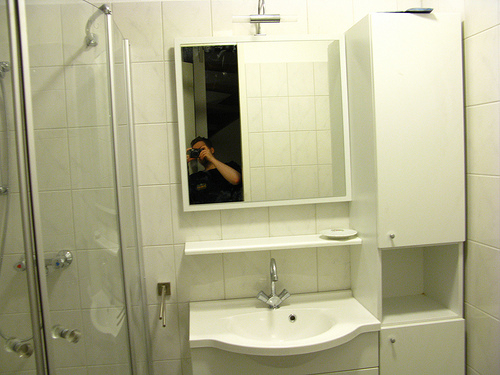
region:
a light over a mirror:
[234, 8, 284, 28]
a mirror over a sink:
[164, 29, 354, 212]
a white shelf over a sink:
[180, 225, 358, 260]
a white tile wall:
[165, 256, 266, 296]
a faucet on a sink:
[261, 254, 294, 310]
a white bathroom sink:
[181, 280, 381, 360]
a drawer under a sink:
[189, 328, 387, 374]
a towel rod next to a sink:
[153, 272, 176, 334]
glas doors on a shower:
[1, 3, 158, 373]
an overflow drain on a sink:
[284, 310, 299, 321]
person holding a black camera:
[185, 133, 240, 203]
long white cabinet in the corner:
[344, 18, 475, 255]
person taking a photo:
[183, 131, 242, 201]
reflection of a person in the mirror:
[183, 135, 242, 202]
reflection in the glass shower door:
[74, 188, 127, 356]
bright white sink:
[186, 288, 374, 357]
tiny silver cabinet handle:
[383, 230, 403, 244]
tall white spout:
[251, 259, 296, 311]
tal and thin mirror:
[179, 46, 256, 208]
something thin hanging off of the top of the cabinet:
[382, 5, 432, 17]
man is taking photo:
[173, 123, 298, 210]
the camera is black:
[182, 136, 207, 165]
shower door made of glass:
[1, 1, 175, 373]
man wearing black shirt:
[184, 160, 249, 218]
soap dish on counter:
[299, 211, 391, 256]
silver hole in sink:
[279, 309, 304, 326]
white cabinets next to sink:
[343, 8, 498, 373]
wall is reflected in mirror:
[240, 59, 340, 194]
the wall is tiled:
[130, 4, 492, 365]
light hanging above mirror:
[230, 2, 301, 41]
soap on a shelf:
[313, 225, 361, 242]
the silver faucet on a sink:
[256, 254, 293, 307]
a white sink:
[183, 284, 383, 356]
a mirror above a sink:
[170, 33, 357, 207]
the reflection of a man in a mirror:
[180, 119, 244, 201]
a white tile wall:
[149, 212, 225, 293]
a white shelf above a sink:
[178, 219, 366, 267]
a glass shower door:
[2, 2, 157, 373]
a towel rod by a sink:
[156, 275, 177, 333]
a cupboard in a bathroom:
[342, 9, 475, 251]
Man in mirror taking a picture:
[158, 58, 245, 206]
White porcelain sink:
[167, 270, 344, 372]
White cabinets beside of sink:
[363, 57, 488, 372]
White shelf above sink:
[175, 227, 378, 247]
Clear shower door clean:
[9, 47, 176, 374]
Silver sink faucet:
[250, 255, 305, 312]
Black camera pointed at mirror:
[182, 145, 201, 165]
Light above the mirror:
[227, 15, 329, 42]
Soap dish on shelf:
[317, 221, 362, 254]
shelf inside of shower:
[75, 185, 147, 368]